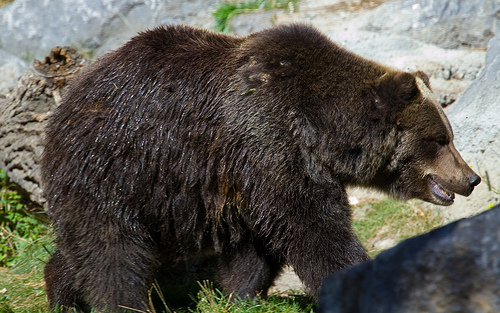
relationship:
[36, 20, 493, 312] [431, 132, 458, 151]
bear has eyes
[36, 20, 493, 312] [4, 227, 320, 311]
bear on grass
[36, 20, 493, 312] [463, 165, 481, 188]
bear has nose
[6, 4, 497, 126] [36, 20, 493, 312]
rocks near bear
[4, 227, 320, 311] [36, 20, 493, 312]
grass near bear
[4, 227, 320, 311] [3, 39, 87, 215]
grass near log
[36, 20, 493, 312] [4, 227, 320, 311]
bear in grass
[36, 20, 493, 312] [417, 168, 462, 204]
bear has mouth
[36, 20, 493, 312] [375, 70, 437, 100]
bear has ears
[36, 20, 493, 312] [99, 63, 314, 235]
bear has fur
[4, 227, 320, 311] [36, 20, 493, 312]
grass under bear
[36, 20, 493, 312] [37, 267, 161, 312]
bear has feet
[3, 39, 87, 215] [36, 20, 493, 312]
log near bear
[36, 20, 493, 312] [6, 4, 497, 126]
bear near rocks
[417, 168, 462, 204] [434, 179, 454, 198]
mouth has teeth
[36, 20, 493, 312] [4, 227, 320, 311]
bear near grass